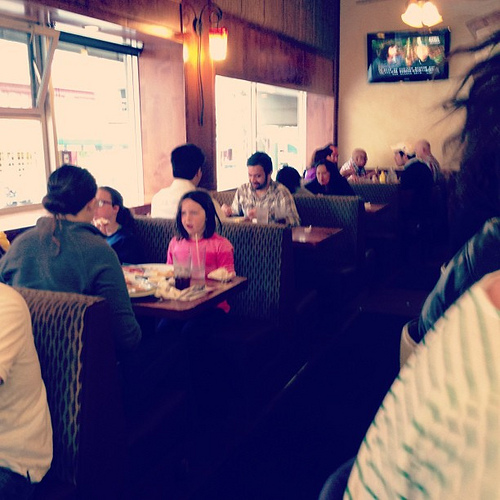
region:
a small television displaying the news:
[366, 29, 449, 81]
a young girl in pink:
[161, 187, 239, 279]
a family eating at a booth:
[1, 168, 288, 352]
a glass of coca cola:
[171, 253, 191, 290]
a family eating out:
[310, 132, 436, 201]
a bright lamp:
[190, 6, 229, 128]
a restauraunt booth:
[0, 258, 119, 499]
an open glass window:
[0, 15, 171, 227]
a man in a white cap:
[390, 144, 430, 239]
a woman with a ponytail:
[5, 160, 132, 352]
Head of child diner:
[176, 189, 217, 238]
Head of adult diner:
[40, 160, 100, 222]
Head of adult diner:
[169, 143, 206, 187]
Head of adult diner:
[244, 151, 274, 193]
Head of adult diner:
[311, 160, 338, 186]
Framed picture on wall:
[361, 24, 456, 89]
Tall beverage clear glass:
[171, 253, 193, 290]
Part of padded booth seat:
[237, 231, 282, 278]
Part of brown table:
[310, 231, 327, 241]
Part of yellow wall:
[374, 99, 421, 124]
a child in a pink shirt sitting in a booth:
[161, 178, 246, 365]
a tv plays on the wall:
[357, 20, 474, 155]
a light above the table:
[191, 15, 273, 82]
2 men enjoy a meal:
[158, 123, 353, 250]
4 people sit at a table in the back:
[310, 127, 465, 217]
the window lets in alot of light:
[6, 60, 142, 210]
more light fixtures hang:
[383, 1, 451, 34]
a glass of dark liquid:
[163, 262, 215, 301]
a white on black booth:
[23, 285, 130, 465]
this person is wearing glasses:
[86, 166, 151, 261]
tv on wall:
[366, 28, 451, 80]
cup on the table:
[173, 248, 192, 285]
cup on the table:
[193, 245, 206, 285]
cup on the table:
[254, 198, 271, 223]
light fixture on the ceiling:
[392, 0, 448, 28]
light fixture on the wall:
[188, 7, 233, 114]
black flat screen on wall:
[365, 32, 448, 82]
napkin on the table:
[163, 280, 180, 300]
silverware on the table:
[175, 275, 200, 302]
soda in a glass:
[174, 253, 187, 286]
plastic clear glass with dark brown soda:
[173, 253, 190, 288]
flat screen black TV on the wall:
[366, 28, 448, 82]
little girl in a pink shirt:
[166, 189, 236, 311]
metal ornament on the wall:
[178, 2, 223, 125]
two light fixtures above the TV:
[399, 2, 441, 28]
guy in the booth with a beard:
[223, 152, 297, 225]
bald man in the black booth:
[340, 148, 368, 176]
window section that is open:
[1, 17, 60, 114]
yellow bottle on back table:
[378, 170, 386, 182]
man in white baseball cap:
[391, 140, 432, 187]